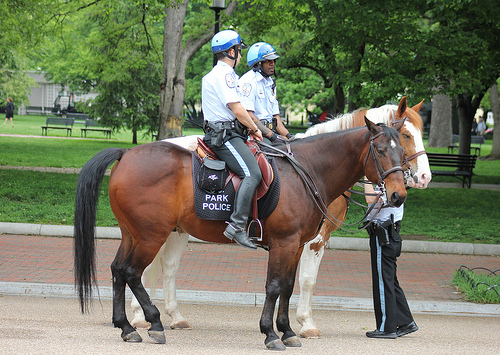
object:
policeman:
[197, 24, 274, 253]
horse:
[69, 115, 421, 343]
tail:
[71, 147, 125, 320]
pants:
[201, 129, 264, 227]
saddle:
[195, 130, 278, 246]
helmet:
[208, 28, 245, 55]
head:
[361, 115, 410, 209]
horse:
[128, 90, 433, 341]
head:
[381, 96, 433, 190]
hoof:
[263, 339, 285, 352]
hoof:
[280, 334, 303, 348]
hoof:
[145, 330, 167, 344]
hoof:
[122, 332, 143, 342]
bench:
[41, 116, 75, 137]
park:
[4, 0, 499, 254]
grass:
[2, 117, 498, 243]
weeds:
[454, 268, 497, 302]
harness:
[318, 195, 379, 226]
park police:
[199, 190, 231, 213]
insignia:
[225, 72, 236, 88]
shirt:
[199, 59, 243, 121]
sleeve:
[214, 73, 241, 108]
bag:
[199, 157, 226, 193]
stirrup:
[246, 220, 264, 242]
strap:
[233, 46, 238, 68]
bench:
[80, 119, 113, 139]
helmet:
[245, 40, 279, 65]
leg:
[257, 233, 298, 337]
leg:
[124, 229, 164, 331]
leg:
[293, 236, 323, 330]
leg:
[159, 236, 186, 323]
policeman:
[236, 39, 295, 149]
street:
[0, 220, 500, 317]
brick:
[200, 282, 211, 288]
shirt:
[238, 74, 288, 127]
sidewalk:
[0, 291, 499, 353]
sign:
[189, 149, 245, 223]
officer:
[367, 179, 423, 339]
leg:
[219, 135, 262, 230]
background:
[4, 0, 500, 248]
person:
[474, 115, 492, 144]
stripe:
[223, 139, 252, 176]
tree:
[384, 3, 497, 170]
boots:
[223, 176, 259, 250]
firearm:
[204, 120, 225, 148]